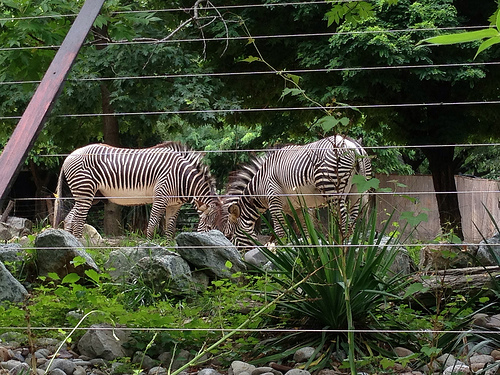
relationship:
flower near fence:
[285, 134, 498, 311] [1, 0, 498, 372]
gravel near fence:
[0, 314, 497, 374] [1, 0, 498, 372]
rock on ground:
[127, 252, 202, 302] [5, 220, 497, 374]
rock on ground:
[243, 241, 285, 269] [5, 220, 497, 374]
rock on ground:
[32, 227, 97, 274] [5, 220, 497, 374]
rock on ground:
[105, 239, 175, 279] [5, 220, 497, 374]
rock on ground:
[172, 230, 249, 282] [5, 220, 497, 374]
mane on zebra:
[151, 139, 221, 200] [52, 140, 242, 244]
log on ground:
[412, 257, 499, 295] [5, 220, 497, 374]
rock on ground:
[243, 241, 285, 269] [15, 209, 299, 293]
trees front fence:
[0, 0, 499, 246] [1, 0, 498, 372]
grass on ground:
[32, 268, 421, 366] [5, 220, 497, 374]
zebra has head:
[221, 133, 375, 258] [189, 191, 244, 248]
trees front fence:
[0, 0, 499, 246] [472, 1, 481, 333]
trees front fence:
[92, 26, 122, 141] [472, 1, 481, 333]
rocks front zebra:
[4, 224, 295, 302] [88, 143, 402, 237]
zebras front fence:
[52, 133, 371, 246] [6, 14, 498, 345]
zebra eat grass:
[221, 133, 375, 258] [83, 226, 178, 251]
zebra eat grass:
[52, 140, 242, 244] [83, 226, 178, 251]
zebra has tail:
[221, 133, 375, 258] [348, 148, 370, 211]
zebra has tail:
[52, 140, 242, 244] [45, 160, 66, 237]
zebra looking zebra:
[221, 133, 375, 258] [52, 137, 228, 240]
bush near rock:
[246, 179, 440, 374] [34, 223, 108, 292]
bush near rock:
[246, 179, 440, 374] [103, 244, 203, 299]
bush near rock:
[246, 179, 440, 374] [183, 224, 247, 276]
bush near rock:
[246, 179, 440, 374] [240, 239, 286, 277]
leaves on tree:
[422, 64, 472, 87] [0, 0, 499, 246]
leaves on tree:
[369, 41, 396, 58] [0, 0, 499, 246]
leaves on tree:
[337, 15, 364, 29] [0, 0, 499, 246]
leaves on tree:
[164, 88, 197, 100] [0, 0, 499, 246]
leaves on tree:
[7, 55, 29, 77] [0, 0, 499, 246]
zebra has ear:
[46, 140, 238, 250] [200, 197, 220, 216]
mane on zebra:
[176, 143, 220, 185] [64, 138, 239, 268]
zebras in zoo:
[6, 72, 448, 314] [9, 1, 499, 373]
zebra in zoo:
[221, 127, 401, 278] [9, 1, 499, 373]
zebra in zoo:
[52, 140, 242, 244] [9, 1, 499, 373]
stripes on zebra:
[284, 159, 313, 186] [221, 133, 375, 258]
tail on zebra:
[331, 137, 396, 197] [221, 133, 375, 258]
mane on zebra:
[226, 150, 273, 203] [219, 130, 376, 257]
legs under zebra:
[140, 184, 187, 241] [46, 140, 238, 250]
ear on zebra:
[226, 198, 243, 221] [219, 130, 376, 257]